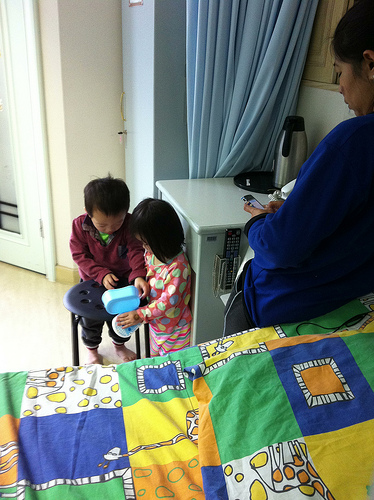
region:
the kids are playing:
[69, 180, 191, 368]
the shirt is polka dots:
[132, 249, 199, 346]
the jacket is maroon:
[66, 223, 157, 294]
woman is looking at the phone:
[241, 55, 368, 256]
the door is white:
[8, 115, 81, 275]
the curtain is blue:
[175, 18, 288, 224]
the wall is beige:
[57, 47, 113, 170]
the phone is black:
[222, 174, 277, 230]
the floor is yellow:
[0, 274, 70, 369]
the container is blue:
[88, 274, 169, 380]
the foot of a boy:
[112, 341, 140, 362]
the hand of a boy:
[100, 272, 121, 290]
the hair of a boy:
[82, 173, 130, 218]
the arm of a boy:
[65, 220, 109, 284]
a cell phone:
[238, 190, 267, 216]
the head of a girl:
[126, 198, 195, 263]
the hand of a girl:
[114, 308, 146, 334]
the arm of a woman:
[239, 115, 359, 270]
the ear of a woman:
[361, 47, 372, 80]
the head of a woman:
[319, 0, 372, 116]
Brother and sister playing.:
[73, 189, 186, 347]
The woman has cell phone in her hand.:
[239, 188, 257, 225]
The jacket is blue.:
[284, 148, 369, 314]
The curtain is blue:
[177, 10, 269, 173]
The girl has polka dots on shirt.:
[154, 269, 183, 323]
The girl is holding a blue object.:
[101, 280, 145, 335]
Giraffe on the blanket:
[71, 409, 218, 459]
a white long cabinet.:
[116, 13, 165, 195]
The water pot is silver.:
[274, 113, 309, 189]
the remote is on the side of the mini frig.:
[214, 224, 246, 289]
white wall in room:
[59, 10, 109, 170]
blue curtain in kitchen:
[201, 8, 272, 162]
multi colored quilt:
[15, 384, 354, 498]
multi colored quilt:
[234, 336, 359, 493]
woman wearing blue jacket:
[319, 149, 359, 296]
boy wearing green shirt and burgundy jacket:
[77, 231, 133, 270]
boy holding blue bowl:
[106, 286, 134, 308]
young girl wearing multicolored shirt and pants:
[149, 265, 189, 344]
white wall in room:
[3, 75, 45, 189]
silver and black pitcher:
[280, 110, 302, 170]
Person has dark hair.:
[135, 207, 202, 276]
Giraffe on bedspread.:
[95, 416, 223, 475]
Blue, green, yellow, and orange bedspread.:
[26, 404, 290, 486]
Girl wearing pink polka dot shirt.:
[156, 290, 184, 337]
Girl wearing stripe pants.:
[151, 338, 173, 344]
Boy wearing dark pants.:
[81, 331, 100, 347]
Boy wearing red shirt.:
[71, 246, 128, 310]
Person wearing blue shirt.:
[270, 172, 364, 268]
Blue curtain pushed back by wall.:
[183, 27, 348, 155]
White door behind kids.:
[10, 153, 77, 242]